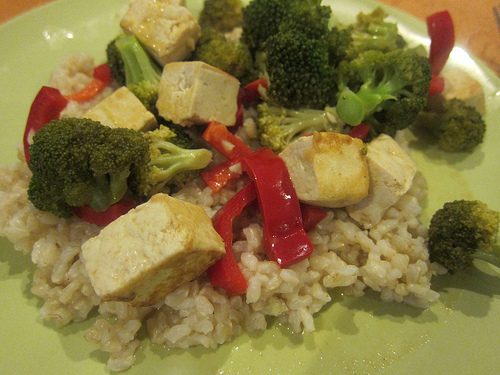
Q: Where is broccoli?
A: On plate.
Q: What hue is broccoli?
A: Green.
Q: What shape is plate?
A: Round.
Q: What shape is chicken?
A: Cube.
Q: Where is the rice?
A: Under stir fry.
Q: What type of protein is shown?
A: Tofu.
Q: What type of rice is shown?
A: White.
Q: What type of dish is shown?
A: Stirfry.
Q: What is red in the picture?
A: Pepper.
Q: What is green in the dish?
A: Broccoli.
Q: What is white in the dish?
A: Tofu.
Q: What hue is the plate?
A: Green.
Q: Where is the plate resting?
A: A table.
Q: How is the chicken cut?
A: In cubes.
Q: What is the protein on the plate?
A: Chicken.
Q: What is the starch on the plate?
A: Rice.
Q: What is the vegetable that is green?
A: Broccoli.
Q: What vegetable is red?
A: Peppers.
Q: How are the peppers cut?
A: In strips.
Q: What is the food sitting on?
A: A plate.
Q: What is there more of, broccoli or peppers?
A: Broccoli.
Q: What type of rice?
A: White.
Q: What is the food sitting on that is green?
A: The plate.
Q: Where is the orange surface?
A: Behind the plate.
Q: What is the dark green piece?
A: Cooked broccoli.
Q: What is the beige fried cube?
A: Tofu.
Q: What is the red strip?
A: Cooked pepper.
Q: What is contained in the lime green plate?
A: Rice and vegetables.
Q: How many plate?
A: 1.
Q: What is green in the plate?
A: Broccoli.